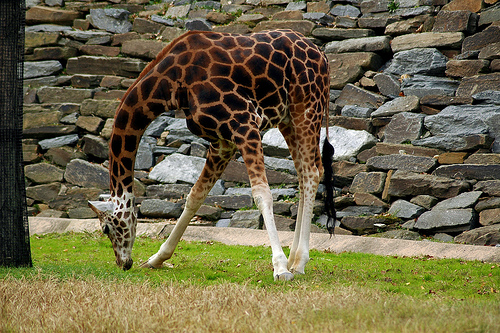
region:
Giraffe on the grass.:
[86, 6, 343, 283]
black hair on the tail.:
[313, 122, 343, 237]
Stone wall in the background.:
[14, 0, 496, 241]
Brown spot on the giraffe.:
[250, 75, 280, 104]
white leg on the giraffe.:
[255, 205, 295, 285]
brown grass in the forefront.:
[2, 274, 494, 331]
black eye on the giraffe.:
[98, 220, 112, 235]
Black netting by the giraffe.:
[0, 2, 36, 273]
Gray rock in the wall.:
[422, 101, 497, 150]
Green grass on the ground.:
[2, 226, 498, 288]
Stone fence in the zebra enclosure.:
[360, 27, 472, 182]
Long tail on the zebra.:
[307, 49, 342, 248]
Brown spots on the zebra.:
[180, 30, 303, 95]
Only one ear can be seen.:
[75, 189, 123, 222]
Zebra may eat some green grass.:
[82, 175, 145, 276]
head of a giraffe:
[68, 159, 148, 284]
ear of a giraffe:
[85, 199, 116, 225]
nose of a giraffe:
[99, 222, 120, 233]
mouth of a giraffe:
[109, 248, 147, 279]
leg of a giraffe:
[132, 195, 239, 289]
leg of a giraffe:
[223, 184, 288, 289]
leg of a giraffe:
[269, 167, 339, 265]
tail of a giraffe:
[317, 116, 362, 223]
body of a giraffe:
[180, 0, 379, 162]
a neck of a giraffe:
[92, 82, 189, 182]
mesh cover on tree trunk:
[1, 0, 30, 265]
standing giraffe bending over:
[88, 28, 334, 282]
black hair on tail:
[321, 83, 335, 234]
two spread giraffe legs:
[144, 136, 291, 280]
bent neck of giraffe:
[109, 49, 178, 197]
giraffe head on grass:
[87, 192, 135, 272]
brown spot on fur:
[245, 53, 267, 76]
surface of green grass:
[33, 234, 495, 288]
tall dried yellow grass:
[1, 275, 498, 329]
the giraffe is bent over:
[87, 30, 338, 287]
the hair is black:
[323, 138, 338, 239]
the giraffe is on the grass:
[0, 29, 498, 329]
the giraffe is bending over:
[89, 35, 381, 295]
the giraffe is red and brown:
[71, 13, 340, 225]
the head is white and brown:
[86, 150, 169, 273]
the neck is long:
[103, 58, 210, 199]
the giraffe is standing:
[112, 25, 383, 307]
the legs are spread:
[197, 158, 341, 298]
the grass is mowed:
[172, 235, 288, 277]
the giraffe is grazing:
[70, 137, 202, 286]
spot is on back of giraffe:
[182, 33, 211, 50]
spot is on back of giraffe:
[212, 35, 237, 50]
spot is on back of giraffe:
[236, 35, 255, 50]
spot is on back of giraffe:
[252, 43, 273, 60]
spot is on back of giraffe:
[272, 35, 293, 55]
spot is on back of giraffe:
[305, 46, 321, 63]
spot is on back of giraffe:
[210, 65, 232, 79]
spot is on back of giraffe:
[182, 65, 207, 85]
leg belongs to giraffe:
[144, 142, 239, 272]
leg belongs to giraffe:
[235, 128, 293, 283]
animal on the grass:
[15, 18, 374, 286]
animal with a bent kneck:
[30, 12, 387, 293]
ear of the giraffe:
[77, 190, 122, 228]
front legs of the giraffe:
[125, 145, 298, 310]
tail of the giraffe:
[303, 88, 378, 240]